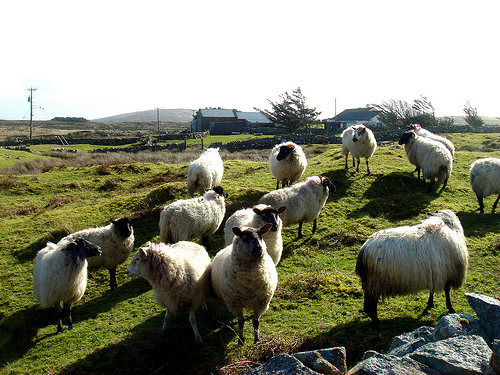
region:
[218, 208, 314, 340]
the sheep is looking at the camera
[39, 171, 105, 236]
the grass is green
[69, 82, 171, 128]
the sky is white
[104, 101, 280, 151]
hill in the distance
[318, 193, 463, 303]
the fur is white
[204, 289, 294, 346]
the legs are black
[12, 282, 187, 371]
shadows on the ground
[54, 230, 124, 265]
the face is black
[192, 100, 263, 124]
the roof is gray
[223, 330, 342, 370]
the rocks are gray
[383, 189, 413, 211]
part of a shade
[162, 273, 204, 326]
neck of a sheep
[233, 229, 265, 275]
head of a sheep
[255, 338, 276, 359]
part of a thicket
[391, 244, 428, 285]
stomach of a sheep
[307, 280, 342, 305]
part of some grass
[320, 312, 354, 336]
edge of a sheep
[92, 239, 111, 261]
nose of a sheep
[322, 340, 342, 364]
edge of a rock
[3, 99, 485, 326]
White sheep in a field.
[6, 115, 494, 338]
Fourteen sheep in a field.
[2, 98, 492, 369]
There are fourteen sheep.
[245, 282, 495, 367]
Small rock wall in the field.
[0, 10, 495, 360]
Photo taken during the day.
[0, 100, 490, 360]
The grass is green.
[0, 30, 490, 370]
Nobody in the field with the sheep.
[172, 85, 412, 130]
Buildings in the background.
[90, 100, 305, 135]
Hill in the background.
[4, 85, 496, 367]
No black sheep in the field.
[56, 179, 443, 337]
Sheep in the field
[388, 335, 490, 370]
Big rocks on the side.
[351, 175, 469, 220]
The grass is green.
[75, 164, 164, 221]
Patches of dirt in the grass.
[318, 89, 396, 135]
a house in the background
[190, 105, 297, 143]
A barn is in the background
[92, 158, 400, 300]
Sheep are standing in the grass.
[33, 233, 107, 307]
The sheep has a black face.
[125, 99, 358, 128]
Hills in the background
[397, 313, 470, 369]
The rocks are gray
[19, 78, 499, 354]
Fourteen wooly sheep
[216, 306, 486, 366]
Rocks in the foreground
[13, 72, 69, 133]
Telephone pole in the distance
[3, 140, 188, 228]
Rich green grass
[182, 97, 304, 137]
Barn in the distance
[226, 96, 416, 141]
House close by the barn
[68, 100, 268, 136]
Mountainous in the background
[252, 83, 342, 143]
A tree stands alone.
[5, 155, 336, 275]
Very uneven terrain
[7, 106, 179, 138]
Not as much grass in the distance